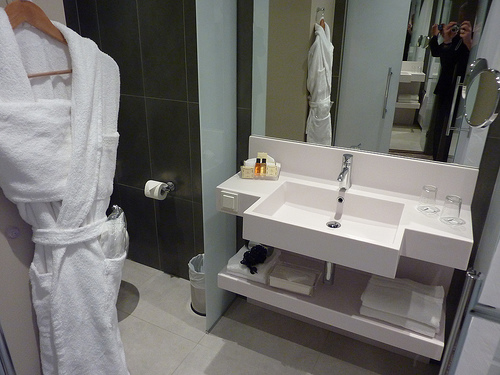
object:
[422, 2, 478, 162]
man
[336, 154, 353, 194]
fixture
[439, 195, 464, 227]
cup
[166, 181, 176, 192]
dispenser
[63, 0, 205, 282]
wall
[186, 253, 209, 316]
trash bin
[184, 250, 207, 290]
plastic liner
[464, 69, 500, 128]
mirror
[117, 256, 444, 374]
ground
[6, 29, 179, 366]
robe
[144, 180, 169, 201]
paper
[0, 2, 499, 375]
bathroom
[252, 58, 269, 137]
wall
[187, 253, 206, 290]
liner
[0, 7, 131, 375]
white bathrobe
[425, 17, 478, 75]
reflection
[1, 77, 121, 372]
robe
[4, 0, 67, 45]
hanger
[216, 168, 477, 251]
counter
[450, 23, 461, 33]
camera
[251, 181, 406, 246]
sink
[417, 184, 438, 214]
glass